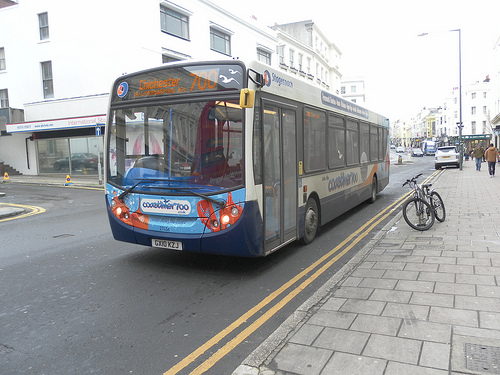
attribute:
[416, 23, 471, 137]
lamp — tall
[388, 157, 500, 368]
sidewalk — bricked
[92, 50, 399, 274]
bus — blue, yellow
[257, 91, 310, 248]
glass door — closed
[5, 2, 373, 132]
building — white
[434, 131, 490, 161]
storefront — large, glass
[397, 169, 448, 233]
bike — parked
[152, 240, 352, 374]
lines — yellow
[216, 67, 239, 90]
seagulls — white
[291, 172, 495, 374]
bricks — grey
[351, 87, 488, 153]
background — overexposed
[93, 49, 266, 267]
bus front — blue, red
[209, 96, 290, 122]
lights — light on